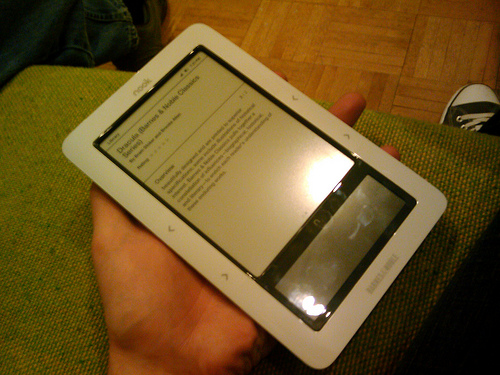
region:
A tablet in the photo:
[182, 165, 399, 316]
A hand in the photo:
[67, 229, 233, 369]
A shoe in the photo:
[434, 92, 490, 129]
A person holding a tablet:
[15, 23, 412, 365]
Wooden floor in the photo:
[348, 25, 435, 87]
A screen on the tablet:
[135, 99, 369, 251]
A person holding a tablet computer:
[93, 26, 443, 330]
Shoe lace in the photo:
[457, 113, 487, 134]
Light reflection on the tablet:
[310, 152, 367, 207]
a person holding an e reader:
[75, 48, 433, 355]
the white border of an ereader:
[235, 282, 327, 344]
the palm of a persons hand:
[94, 226, 242, 356]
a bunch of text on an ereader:
[132, 96, 276, 200]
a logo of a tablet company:
[364, 245, 404, 305]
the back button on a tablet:
[201, 253, 249, 311]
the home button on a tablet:
[150, 222, 184, 253]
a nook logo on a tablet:
[124, 61, 162, 108]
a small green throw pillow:
[2, 158, 69, 305]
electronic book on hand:
[62, 19, 450, 372]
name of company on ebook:
[131, 75, 153, 97]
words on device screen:
[113, 65, 273, 216]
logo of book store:
[365, 250, 400, 297]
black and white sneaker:
[439, 82, 498, 127]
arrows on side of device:
[166, 223, 231, 288]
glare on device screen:
[298, 288, 329, 319]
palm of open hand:
[117, 230, 259, 350]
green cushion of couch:
[3, 61, 497, 369]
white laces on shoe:
[457, 110, 494, 130]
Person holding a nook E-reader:
[50, 25, 480, 361]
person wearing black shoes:
[448, 76, 493, 142]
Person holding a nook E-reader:
[220, 153, 477, 320]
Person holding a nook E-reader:
[76, 63, 343, 234]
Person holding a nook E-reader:
[12, 15, 472, 199]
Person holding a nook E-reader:
[163, 232, 481, 373]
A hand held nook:
[57, 20, 450, 372]